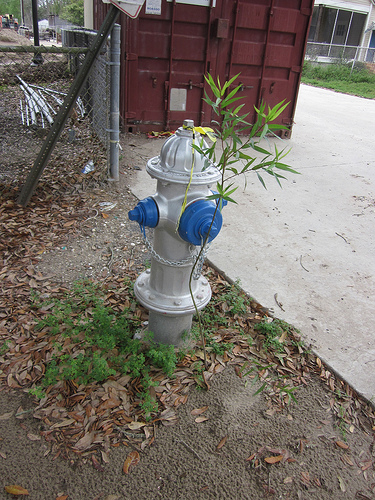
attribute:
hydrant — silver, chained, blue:
[116, 118, 230, 333]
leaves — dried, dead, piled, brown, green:
[5, 182, 126, 292]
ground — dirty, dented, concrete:
[2, 199, 360, 493]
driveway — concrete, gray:
[125, 63, 372, 381]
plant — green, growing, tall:
[182, 78, 275, 309]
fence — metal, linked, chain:
[2, 22, 113, 184]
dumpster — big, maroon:
[102, 0, 305, 136]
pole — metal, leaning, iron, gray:
[102, 27, 127, 194]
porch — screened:
[309, 1, 374, 76]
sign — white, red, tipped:
[108, 1, 149, 22]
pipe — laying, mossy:
[21, 18, 109, 175]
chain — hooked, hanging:
[134, 219, 218, 272]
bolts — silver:
[138, 264, 211, 308]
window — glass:
[312, 2, 335, 37]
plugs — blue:
[126, 191, 236, 243]